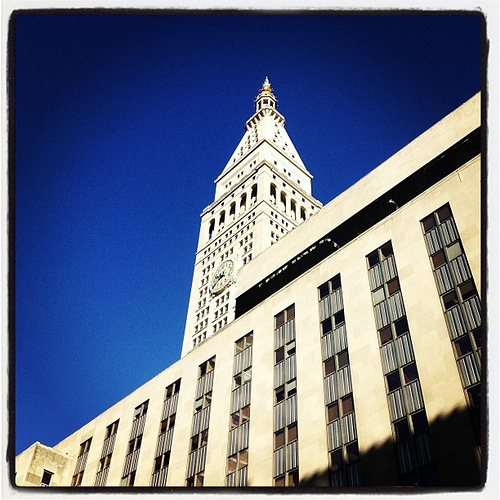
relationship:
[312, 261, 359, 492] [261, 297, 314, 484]
windows in line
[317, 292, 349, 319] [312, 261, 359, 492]
squares under windows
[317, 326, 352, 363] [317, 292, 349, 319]
ridges on squares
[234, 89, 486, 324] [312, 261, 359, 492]
platform above windows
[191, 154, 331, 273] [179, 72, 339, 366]
arches on tower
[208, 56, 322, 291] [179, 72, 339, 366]
narrow point tower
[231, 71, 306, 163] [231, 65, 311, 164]
top building top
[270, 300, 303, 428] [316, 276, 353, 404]
window on building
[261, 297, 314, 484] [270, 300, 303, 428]
three window window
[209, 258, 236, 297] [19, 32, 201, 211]
clock blue sky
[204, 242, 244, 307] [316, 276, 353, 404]
clock on building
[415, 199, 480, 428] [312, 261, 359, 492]
row of windows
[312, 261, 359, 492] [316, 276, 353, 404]
windows on building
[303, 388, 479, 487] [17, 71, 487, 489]
shadow on building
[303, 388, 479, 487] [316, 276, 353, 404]
shadow across building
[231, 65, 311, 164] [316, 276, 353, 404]
top of building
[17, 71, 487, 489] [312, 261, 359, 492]
rectangular building windows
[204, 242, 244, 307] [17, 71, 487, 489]
clock on building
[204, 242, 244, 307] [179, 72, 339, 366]
clock on tower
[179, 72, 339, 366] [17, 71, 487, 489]
tower atop building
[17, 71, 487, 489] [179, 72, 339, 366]
building with tower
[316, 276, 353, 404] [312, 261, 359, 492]
building has windows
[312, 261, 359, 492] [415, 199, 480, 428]
windows in row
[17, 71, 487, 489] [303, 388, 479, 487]
building with shadow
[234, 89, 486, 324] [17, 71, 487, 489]
stripe on building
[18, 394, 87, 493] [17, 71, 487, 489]
part of building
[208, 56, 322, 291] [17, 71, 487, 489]
portion of building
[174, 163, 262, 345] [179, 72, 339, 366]
windows on tower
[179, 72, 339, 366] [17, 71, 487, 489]
tower on building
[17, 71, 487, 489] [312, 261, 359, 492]
buildng has windows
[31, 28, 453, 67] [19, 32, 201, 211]
blue in sky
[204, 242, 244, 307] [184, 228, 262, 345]
clock at front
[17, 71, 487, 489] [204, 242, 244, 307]
white building clock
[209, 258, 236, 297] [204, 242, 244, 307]
clock white clock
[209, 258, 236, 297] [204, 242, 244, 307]
clock on clock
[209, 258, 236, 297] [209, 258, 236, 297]
clock clock clock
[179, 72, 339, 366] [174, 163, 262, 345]
tower with windows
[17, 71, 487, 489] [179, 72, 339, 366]
white on tower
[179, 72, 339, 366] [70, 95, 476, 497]
clock on building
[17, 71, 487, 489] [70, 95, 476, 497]
windows on building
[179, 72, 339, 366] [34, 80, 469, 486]
tower on building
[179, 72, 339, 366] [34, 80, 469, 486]
clock on building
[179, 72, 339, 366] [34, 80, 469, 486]
tiers on building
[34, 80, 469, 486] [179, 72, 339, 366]
building has tiers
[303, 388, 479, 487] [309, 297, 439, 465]
shadow on wall